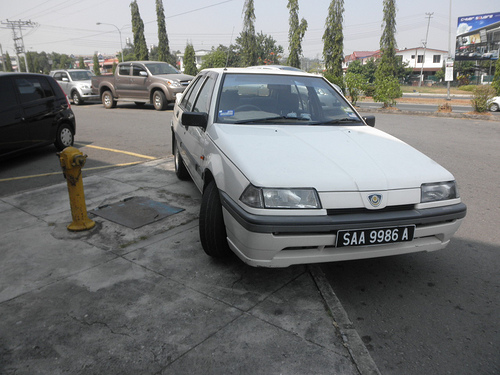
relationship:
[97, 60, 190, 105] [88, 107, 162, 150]
truck parked on street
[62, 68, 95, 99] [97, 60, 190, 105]
car parked behind truck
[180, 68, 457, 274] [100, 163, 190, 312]
car parked on curb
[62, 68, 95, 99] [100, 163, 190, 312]
car parked on curb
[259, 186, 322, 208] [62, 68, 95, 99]
headlight of car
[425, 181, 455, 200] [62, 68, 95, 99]
headlight of car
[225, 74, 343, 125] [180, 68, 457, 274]
windshield of car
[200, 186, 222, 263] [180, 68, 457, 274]
front wheel of car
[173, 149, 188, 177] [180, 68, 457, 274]
rear wheel of car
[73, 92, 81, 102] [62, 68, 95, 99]
front wheel of car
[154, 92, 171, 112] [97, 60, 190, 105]
tire on truck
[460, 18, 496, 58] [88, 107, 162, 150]
sign next to street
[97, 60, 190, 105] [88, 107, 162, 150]
truck driving on street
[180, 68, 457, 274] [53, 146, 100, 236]
car parked on near hydrant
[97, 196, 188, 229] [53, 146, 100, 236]
grate next to hydrant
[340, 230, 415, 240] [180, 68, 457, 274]
license plate mounted on car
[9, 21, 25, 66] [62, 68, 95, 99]
power pole behind car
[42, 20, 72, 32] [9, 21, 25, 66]
wire attached to power pole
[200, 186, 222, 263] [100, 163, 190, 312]
front wheel on top of curb